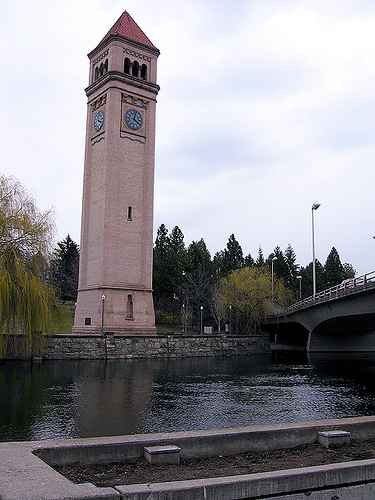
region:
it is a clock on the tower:
[124, 111, 144, 128]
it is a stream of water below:
[146, 381, 195, 422]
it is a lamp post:
[98, 294, 118, 330]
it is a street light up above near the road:
[310, 199, 332, 298]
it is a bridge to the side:
[295, 302, 353, 343]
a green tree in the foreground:
[4, 182, 69, 318]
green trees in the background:
[157, 227, 199, 279]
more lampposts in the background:
[177, 306, 208, 326]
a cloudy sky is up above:
[199, 122, 253, 180]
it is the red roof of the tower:
[104, 15, 148, 44]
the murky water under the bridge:
[1, 360, 373, 439]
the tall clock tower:
[64, 6, 162, 348]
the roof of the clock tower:
[86, 8, 166, 55]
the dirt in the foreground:
[50, 436, 373, 486]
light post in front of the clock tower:
[97, 285, 108, 330]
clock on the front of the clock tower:
[124, 105, 146, 137]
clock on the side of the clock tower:
[92, 110, 107, 135]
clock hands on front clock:
[133, 114, 139, 123]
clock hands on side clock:
[96, 115, 101, 123]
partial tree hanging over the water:
[2, 174, 68, 360]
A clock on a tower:
[119, 103, 147, 133]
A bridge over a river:
[264, 260, 374, 366]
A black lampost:
[97, 291, 112, 332]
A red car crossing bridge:
[340, 277, 366, 290]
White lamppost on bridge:
[306, 197, 328, 302]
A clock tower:
[71, 14, 156, 344]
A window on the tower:
[121, 204, 137, 219]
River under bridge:
[3, 351, 373, 451]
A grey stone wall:
[11, 332, 271, 360]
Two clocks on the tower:
[88, 103, 147, 140]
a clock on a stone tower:
[117, 99, 148, 140]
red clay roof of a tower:
[94, 9, 169, 58]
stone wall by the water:
[70, 331, 229, 369]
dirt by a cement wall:
[194, 438, 318, 484]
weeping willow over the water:
[15, 242, 88, 373]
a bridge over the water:
[255, 299, 373, 367]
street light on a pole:
[309, 191, 337, 299]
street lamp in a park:
[195, 302, 212, 340]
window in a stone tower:
[107, 180, 148, 237]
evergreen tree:
[319, 245, 349, 279]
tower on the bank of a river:
[33, 8, 340, 451]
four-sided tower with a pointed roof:
[60, 2, 168, 340]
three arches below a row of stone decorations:
[113, 38, 152, 83]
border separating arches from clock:
[81, 50, 171, 142]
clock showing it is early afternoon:
[109, 95, 154, 151]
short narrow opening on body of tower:
[112, 142, 141, 269]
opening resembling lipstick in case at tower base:
[113, 282, 139, 327]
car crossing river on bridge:
[230, 256, 366, 361]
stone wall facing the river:
[35, 321, 287, 366]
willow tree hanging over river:
[4, 182, 64, 407]